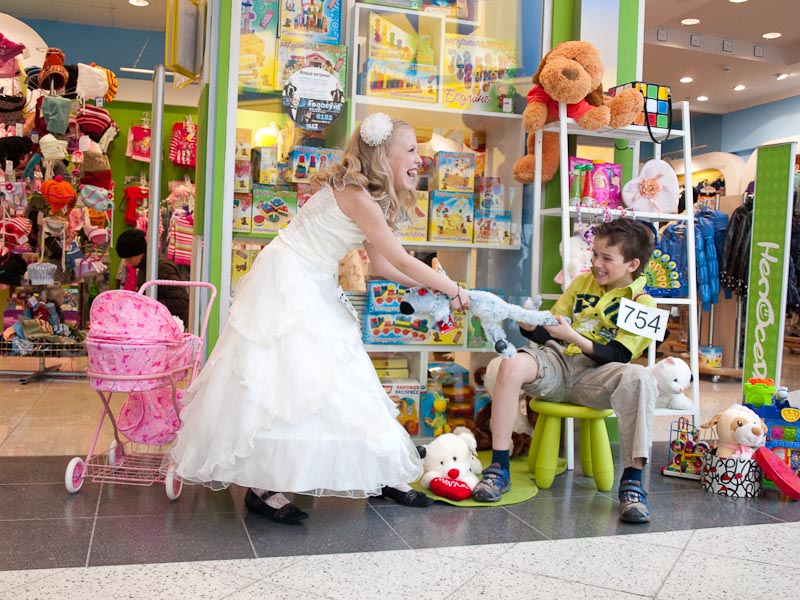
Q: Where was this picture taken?
A: A toy shop.